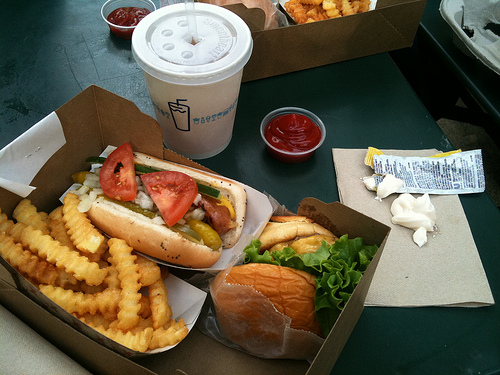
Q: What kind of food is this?
A: Fast food.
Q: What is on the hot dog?
A: It's loaded.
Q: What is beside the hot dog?
A: French fries.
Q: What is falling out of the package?
A: Mayo.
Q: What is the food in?
A: Box.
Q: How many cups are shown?
A: One.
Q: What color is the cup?
A: White.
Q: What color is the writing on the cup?
A: Blue.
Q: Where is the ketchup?
A: Beside the cup.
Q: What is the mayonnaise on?
A: Napkin.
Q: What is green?
A: Lettuce.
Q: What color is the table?
A: Green.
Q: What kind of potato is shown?
A: French fries.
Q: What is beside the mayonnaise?
A: Packet.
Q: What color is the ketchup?
A: Red.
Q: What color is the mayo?
A: White.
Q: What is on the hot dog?
A: Tomatoes and veggies.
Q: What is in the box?
A: Hotdog, burger, and fries.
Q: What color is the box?
A: Brown.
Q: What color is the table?
A: Brown.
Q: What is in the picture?
A: Food.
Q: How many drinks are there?
A: 1.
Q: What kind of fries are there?
A: Crinkle cut.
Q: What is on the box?
A: Stapled receipt.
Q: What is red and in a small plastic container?
A: Ketchup.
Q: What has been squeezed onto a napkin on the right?
A: Mayonnaise.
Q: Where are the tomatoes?
A: On the hot dog.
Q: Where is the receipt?
A: Stapled to the box.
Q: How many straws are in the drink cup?
A: 1.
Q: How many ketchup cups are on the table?
A: 2.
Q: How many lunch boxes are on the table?
A: 2.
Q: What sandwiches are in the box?
A: Hotdog and hamburger.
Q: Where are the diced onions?
A: On the hotdog.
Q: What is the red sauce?
A: Ketchup.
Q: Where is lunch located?
A: On the table.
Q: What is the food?
A: A hot dog, a hamburger, and french fries.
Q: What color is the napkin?
A: White.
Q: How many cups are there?
A: One.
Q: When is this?
A: Lunchtime.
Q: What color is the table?
A: Green.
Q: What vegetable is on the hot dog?
A: Tomato.